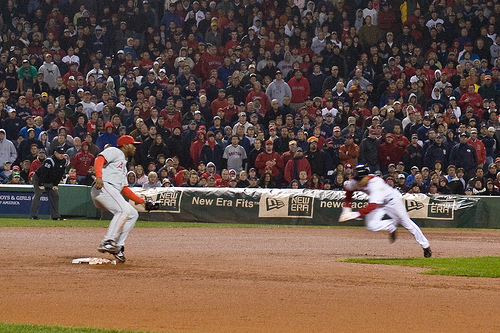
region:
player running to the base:
[336, 159, 435, 260]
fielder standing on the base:
[91, 133, 151, 265]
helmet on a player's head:
[350, 159, 371, 181]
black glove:
[146, 197, 157, 213]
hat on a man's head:
[115, 131, 141, 146]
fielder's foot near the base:
[114, 245, 126, 265]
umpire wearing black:
[27, 145, 69, 222]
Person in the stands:
[285, 145, 312, 190]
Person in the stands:
[260, 154, 285, 193]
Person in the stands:
[231, 154, 253, 184]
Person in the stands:
[220, 129, 242, 168]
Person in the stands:
[257, 60, 295, 106]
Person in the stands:
[290, 62, 317, 102]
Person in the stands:
[307, 59, 327, 102]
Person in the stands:
[460, 81, 477, 114]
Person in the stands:
[433, 74, 450, 109]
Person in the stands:
[36, 52, 60, 96]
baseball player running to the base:
[341, 163, 438, 256]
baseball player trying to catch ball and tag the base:
[91, 131, 153, 264]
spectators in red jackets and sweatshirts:
[256, 136, 311, 179]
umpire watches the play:
[28, 142, 73, 228]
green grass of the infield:
[343, 248, 496, 278]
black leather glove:
[143, 197, 163, 212]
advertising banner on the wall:
[110, 186, 480, 217]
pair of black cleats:
[96, 238, 131, 269]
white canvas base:
[71, 250, 116, 269]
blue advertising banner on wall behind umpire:
[0, 193, 52, 217]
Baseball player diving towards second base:
[335, 163, 432, 256]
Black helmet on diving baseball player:
[347, 162, 374, 179]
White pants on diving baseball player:
[363, 195, 429, 250]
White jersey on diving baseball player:
[345, 177, 400, 200]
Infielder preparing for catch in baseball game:
[90, 132, 161, 260]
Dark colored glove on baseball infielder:
[140, 195, 165, 212]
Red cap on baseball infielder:
[112, 132, 142, 147]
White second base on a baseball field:
[72, 255, 114, 265]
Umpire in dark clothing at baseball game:
[26, 145, 69, 222]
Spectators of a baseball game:
[1, 1, 498, 196]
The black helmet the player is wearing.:
[350, 166, 373, 179]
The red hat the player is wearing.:
[113, 132, 141, 149]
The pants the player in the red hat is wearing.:
[90, 177, 140, 245]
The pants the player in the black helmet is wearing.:
[364, 202, 430, 249]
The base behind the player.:
[74, 257, 111, 267]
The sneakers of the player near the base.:
[92, 245, 126, 260]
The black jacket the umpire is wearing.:
[36, 156, 68, 188]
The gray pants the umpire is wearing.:
[32, 180, 59, 214]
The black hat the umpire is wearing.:
[52, 144, 68, 154]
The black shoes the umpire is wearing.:
[30, 215, 63, 221]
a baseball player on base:
[85, 131, 158, 261]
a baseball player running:
[336, 166, 434, 260]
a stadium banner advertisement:
[111, 186, 481, 228]